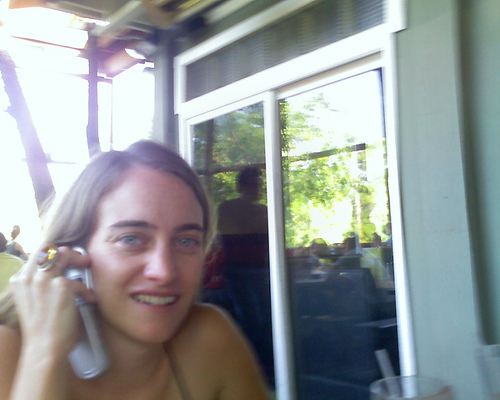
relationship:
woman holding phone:
[1, 135, 274, 399] [52, 245, 117, 383]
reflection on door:
[202, 163, 270, 373] [173, 58, 418, 399]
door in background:
[173, 58, 418, 399] [1, 0, 500, 399]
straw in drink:
[372, 346, 401, 399] [366, 373, 462, 399]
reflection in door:
[202, 163, 270, 373] [173, 58, 418, 399]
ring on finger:
[33, 240, 61, 274] [30, 243, 96, 280]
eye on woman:
[111, 230, 147, 250] [1, 135, 274, 399]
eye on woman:
[168, 232, 203, 252] [1, 135, 274, 399]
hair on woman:
[0, 136, 225, 319] [1, 135, 274, 399]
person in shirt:
[1, 251, 26, 293] [0, 250, 25, 295]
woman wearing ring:
[1, 135, 274, 399] [33, 240, 61, 274]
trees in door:
[193, 77, 388, 260] [173, 58, 418, 399]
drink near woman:
[366, 373, 462, 399] [1, 135, 274, 399]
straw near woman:
[372, 346, 401, 399] [1, 135, 274, 399]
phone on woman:
[52, 245, 117, 383] [1, 135, 274, 399]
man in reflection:
[209, 165, 289, 347] [202, 163, 270, 373]